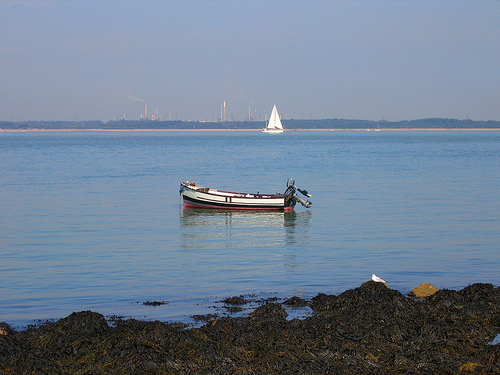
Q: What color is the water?
A: Blue.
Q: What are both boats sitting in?
A: Water.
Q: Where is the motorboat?
A: By the shore.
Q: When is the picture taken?
A: Daytime.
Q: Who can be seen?
A: No one.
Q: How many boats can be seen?
A: 2.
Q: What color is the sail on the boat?
A: White.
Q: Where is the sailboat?
A: In the distance.